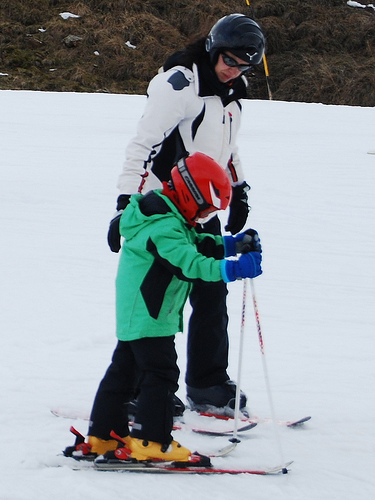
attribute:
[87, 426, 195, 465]
boots — yellow, red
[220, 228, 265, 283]
gloves — blue, black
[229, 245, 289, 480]
ski poles — white, red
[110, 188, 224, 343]
coat — green, black, bright green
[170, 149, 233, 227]
helmet — red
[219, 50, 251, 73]
sunglasses — black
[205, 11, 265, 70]
helmet — black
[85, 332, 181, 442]
ski pants — black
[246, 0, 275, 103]
pole — yellow, black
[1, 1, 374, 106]
grass — brown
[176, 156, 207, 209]
stripes — grey, black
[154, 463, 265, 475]
stripe — red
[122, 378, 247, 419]
snow shoes — black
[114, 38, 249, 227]
coat — white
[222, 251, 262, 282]
right glove — blue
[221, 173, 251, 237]
left glove — black